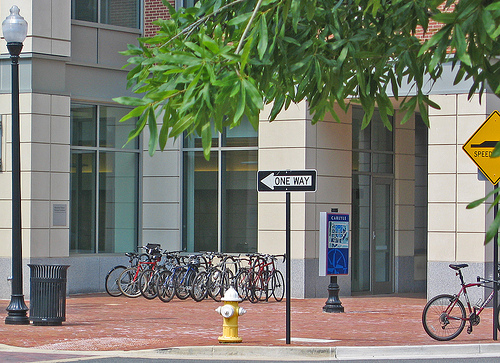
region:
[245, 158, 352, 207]
black and white sign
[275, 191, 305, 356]
dark colored pole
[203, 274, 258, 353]
yellow and white fire hydrant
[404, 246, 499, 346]
red bike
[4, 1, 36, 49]
light on the huge pole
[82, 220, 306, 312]
a group of bikes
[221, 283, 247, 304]
white top of the fire hydrant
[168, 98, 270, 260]
windows on the building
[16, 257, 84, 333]
trash can next to the pole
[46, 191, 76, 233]
sign on the building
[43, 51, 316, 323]
Bicycles parked outside a building.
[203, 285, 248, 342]
A yellow and white fire hydrant.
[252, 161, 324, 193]
A sign pointing to the left.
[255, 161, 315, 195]
Black sign with white arrow.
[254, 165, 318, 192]
Sign saying ONE WAY.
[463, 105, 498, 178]
A yellow sign.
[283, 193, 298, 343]
A black pole support for one way sign.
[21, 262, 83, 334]
A large trash can.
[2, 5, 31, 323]
A tall street lamp.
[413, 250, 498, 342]
A bicycle parked by itself.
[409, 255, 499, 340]
Red and black bike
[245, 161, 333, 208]
Black and white sign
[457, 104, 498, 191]
Yellow and black sign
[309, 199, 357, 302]
Blue and white sign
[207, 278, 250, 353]
Yellow and white fire hydrant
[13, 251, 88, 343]
Metal garbage can container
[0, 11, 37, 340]
Street light on decorative metal pole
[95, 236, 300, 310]
Large group of bikes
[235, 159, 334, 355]
Sign on metal sign post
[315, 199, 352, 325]
Advertisement on metal sign post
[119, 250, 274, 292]
these are several bicycles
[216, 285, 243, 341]
this is a water hose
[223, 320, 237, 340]
the hose is yellow in color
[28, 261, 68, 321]
this is a dustbin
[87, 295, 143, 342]
this is a pavement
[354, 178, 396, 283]
this is a door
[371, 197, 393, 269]
the door is made of glass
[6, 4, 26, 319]
this is a streetlight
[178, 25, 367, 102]
the leaves are green in color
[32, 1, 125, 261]
this is a building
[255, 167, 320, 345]
A one way sign pointing right.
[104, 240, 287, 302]
A bunch of bicycles chained to a rack.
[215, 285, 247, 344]
A yellow fire hydrant at the curb.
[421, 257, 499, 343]
A red bicycle locked to the yellow sign.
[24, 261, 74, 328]
A trash container.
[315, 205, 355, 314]
An information sign.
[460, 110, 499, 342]
A yellow caution sign.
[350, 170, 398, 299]
A door into the office building.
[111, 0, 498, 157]
Branch with lush green leaves.